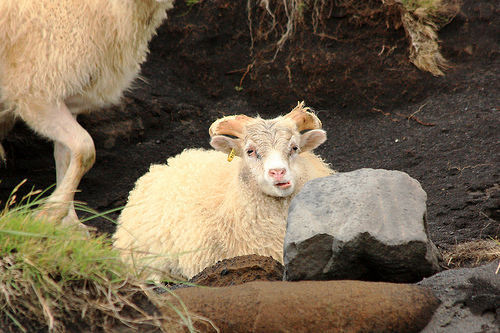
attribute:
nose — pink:
[268, 167, 288, 177]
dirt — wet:
[3, 1, 498, 242]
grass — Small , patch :
[36, 210, 80, 263]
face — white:
[218, 109, 314, 201]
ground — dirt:
[3, 5, 498, 280]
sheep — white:
[124, 84, 391, 286]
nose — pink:
[265, 166, 291, 182]